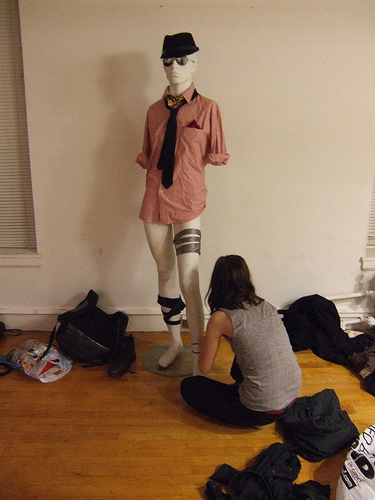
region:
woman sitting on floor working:
[179, 254, 301, 430]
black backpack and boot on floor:
[51, 290, 142, 381]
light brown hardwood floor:
[31, 409, 185, 499]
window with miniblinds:
[0, 1, 42, 267]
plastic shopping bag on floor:
[1, 341, 70, 383]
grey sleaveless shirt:
[234, 308, 299, 404]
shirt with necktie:
[137, 90, 225, 221]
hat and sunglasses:
[159, 32, 198, 65]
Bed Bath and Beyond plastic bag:
[336, 412, 374, 499]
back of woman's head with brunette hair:
[208, 255, 254, 305]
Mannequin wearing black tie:
[134, 31, 227, 379]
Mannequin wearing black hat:
[133, 31, 230, 378]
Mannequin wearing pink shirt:
[133, 33, 230, 376]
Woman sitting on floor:
[182, 250, 300, 430]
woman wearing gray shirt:
[177, 254, 300, 428]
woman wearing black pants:
[179, 251, 302, 429]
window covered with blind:
[0, 0, 38, 253]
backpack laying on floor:
[33, 290, 134, 377]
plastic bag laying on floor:
[334, 424, 372, 497]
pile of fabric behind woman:
[276, 388, 360, 463]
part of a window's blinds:
[0, 0, 38, 252]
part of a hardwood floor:
[0, 375, 171, 498]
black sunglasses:
[161, 56, 190, 67]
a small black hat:
[160, 30, 197, 61]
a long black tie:
[158, 90, 198, 190]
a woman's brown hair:
[203, 253, 263, 311]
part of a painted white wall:
[241, 6, 373, 168]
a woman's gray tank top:
[220, 294, 301, 411]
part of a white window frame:
[2, 247, 45, 271]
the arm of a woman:
[198, 313, 229, 373]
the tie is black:
[158, 109, 178, 184]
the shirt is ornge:
[142, 102, 224, 222]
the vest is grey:
[233, 310, 297, 412]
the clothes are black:
[291, 396, 355, 449]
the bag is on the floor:
[49, 289, 134, 365]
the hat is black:
[151, 29, 197, 58]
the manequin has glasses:
[134, 32, 225, 372]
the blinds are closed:
[6, 164, 32, 251]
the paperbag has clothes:
[12, 336, 72, 380]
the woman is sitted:
[178, 265, 302, 435]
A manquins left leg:
[178, 208, 209, 369]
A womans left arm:
[196, 313, 235, 382]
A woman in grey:
[221, 298, 305, 407]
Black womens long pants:
[182, 368, 267, 425]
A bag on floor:
[52, 284, 128, 371]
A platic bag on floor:
[9, 332, 83, 390]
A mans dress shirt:
[128, 88, 225, 228]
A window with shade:
[0, 2, 39, 267]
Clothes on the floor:
[188, 429, 335, 498]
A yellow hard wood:
[27, 396, 168, 486]